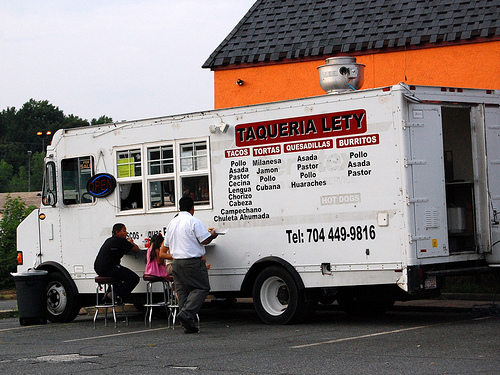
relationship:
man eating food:
[157, 195, 220, 334] [202, 220, 231, 236]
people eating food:
[91, 223, 146, 316] [202, 220, 231, 236]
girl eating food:
[143, 231, 180, 296] [202, 220, 231, 236]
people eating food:
[91, 223, 146, 316] [207, 227, 215, 234]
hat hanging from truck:
[86, 171, 126, 196] [14, 84, 398, 305]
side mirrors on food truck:
[40, 157, 59, 208] [8, 82, 496, 324]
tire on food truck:
[207, 277, 334, 337] [21, 135, 311, 216]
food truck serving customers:
[52, 106, 439, 314] [97, 199, 222, 319]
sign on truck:
[83, 172, 118, 198] [15, 77, 497, 329]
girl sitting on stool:
[143, 231, 180, 296] [141, 270, 173, 323]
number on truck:
[306, 226, 381, 244] [15, 77, 497, 329]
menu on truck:
[209, 122, 369, 227] [15, 77, 497, 329]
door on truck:
[407, 103, 490, 258] [15, 77, 497, 329]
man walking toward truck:
[158, 195, 230, 342] [24, 115, 384, 270]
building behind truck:
[199, 1, 499, 114] [15, 77, 497, 329]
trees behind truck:
[3, 80, 121, 265] [15, 77, 497, 329]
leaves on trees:
[3, 97, 112, 269] [2, 92, 109, 190]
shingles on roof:
[207, 2, 497, 66] [200, 0, 498, 71]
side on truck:
[79, 128, 397, 253] [16, 109, 498, 321]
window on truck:
[111, 143, 145, 213] [15, 77, 497, 329]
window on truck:
[143, 140, 181, 211] [15, 77, 497, 329]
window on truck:
[174, 133, 212, 210] [15, 77, 497, 329]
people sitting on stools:
[91, 233, 233, 325] [84, 273, 184, 323]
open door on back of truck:
[408, 99, 499, 266] [15, 77, 497, 329]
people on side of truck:
[91, 223, 146, 316] [15, 77, 497, 329]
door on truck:
[457, 102, 497, 255] [81, 105, 391, 273]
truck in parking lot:
[27, 128, 454, 255] [7, 295, 482, 352]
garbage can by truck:
[14, 265, 52, 328] [15, 77, 497, 329]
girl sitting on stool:
[134, 231, 191, 296] [137, 269, 192, 333]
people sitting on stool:
[91, 223, 146, 316] [88, 269, 125, 322]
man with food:
[158, 195, 230, 342] [218, 137, 389, 199]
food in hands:
[218, 137, 389, 199] [205, 222, 223, 251]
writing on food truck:
[213, 107, 380, 224] [8, 82, 496, 324]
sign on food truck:
[230, 106, 371, 148] [8, 82, 496, 324]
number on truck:
[284, 224, 384, 242] [9, 81, 497, 302]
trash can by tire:
[11, 271, 51, 323] [44, 270, 79, 319]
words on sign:
[230, 115, 368, 143] [230, 108, 371, 149]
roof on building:
[209, 2, 494, 74] [199, 1, 499, 114]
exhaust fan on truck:
[315, 55, 367, 92] [15, 77, 497, 329]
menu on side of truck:
[209, 107, 369, 228] [4, 46, 498, 331]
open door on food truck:
[413, 99, 498, 267] [436, 96, 497, 261]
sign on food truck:
[83, 172, 118, 198] [8, 82, 496, 324]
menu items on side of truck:
[221, 144, 253, 207] [37, 114, 396, 311]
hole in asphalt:
[29, 344, 102, 368] [16, 317, 498, 371]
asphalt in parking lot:
[16, 317, 498, 371] [9, 282, 499, 366]